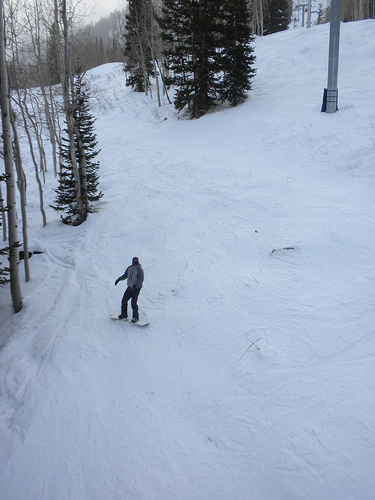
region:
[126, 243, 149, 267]
head of a person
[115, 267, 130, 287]
arm of a person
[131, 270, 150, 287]
arm of a person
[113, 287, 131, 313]
leg of a person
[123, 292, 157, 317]
leg of a person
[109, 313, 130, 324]
feet of a person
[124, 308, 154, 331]
feet of a person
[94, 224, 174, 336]
person on a board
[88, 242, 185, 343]
person wearing a jacket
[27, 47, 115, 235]
tree on a snow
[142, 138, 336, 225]
The snow is the color white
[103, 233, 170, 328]
The man on the slopes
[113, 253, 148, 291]
The man is wearing a gray jacket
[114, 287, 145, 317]
The man is wearing black pants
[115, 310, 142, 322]
The feet of the man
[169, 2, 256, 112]
The tree is very healthy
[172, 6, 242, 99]
The leaves on the tree is green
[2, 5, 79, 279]
The trees have no leaves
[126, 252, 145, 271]
The man has on a hat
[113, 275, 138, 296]
The man is wearing gloves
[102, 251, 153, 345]
A man on the snowboard.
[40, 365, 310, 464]
The snow is white.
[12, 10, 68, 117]
The tree has no leaves.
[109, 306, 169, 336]
The snowboard is white.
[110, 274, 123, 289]
The person is wearing gloves.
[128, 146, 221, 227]
Tracks on the snow.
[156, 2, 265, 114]
The tree is green.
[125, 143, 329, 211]
Snow is covered on the ground.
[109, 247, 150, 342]
Person is going down the hill.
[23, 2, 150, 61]
Trees in the background.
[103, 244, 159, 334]
Man snow boarding on the slope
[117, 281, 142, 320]
Man wearing black pants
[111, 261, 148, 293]
man wearing gray jacket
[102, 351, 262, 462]
snow on the ground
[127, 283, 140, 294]
man wearing black pants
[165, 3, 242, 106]
leaves on the tree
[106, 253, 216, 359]
A person is on the snow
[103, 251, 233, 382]
A person snowboarding on the snow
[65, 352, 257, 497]
A large body of snow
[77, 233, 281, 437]
Large body of snow around the person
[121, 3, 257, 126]
Large trees in the background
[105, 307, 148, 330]
Snowboard a person is on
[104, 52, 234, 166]
Snow is near the trees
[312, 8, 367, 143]
A pole in the snow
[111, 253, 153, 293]
The person has a sweatshirt on